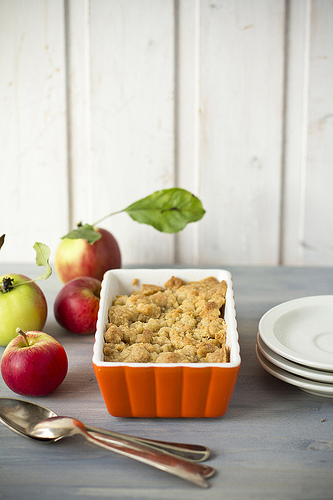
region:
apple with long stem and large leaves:
[54, 173, 207, 274]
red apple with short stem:
[0, 321, 65, 391]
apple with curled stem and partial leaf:
[0, 235, 51, 340]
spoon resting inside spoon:
[0, 393, 215, 486]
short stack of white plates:
[252, 285, 327, 398]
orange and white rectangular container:
[90, 263, 238, 412]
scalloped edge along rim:
[89, 264, 237, 364]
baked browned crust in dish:
[99, 271, 225, 364]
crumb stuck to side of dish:
[129, 270, 141, 288]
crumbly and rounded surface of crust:
[103, 274, 226, 362]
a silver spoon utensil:
[22, 417, 217, 486]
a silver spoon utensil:
[0, 395, 209, 462]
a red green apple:
[2, 325, 69, 396]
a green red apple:
[0, 271, 49, 350]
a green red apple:
[59, 227, 122, 282]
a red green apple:
[54, 277, 98, 334]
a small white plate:
[258, 294, 331, 373]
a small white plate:
[254, 329, 332, 383]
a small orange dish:
[90, 266, 239, 417]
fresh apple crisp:
[70, 247, 273, 438]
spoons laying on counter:
[0, 382, 215, 498]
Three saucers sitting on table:
[252, 279, 329, 440]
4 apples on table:
[0, 217, 123, 414]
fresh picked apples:
[0, 181, 97, 421]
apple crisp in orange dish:
[53, 215, 276, 442]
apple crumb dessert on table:
[90, 237, 251, 439]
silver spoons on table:
[0, 360, 234, 486]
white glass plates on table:
[250, 254, 329, 403]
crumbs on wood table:
[293, 394, 331, 465]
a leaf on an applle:
[127, 187, 204, 234]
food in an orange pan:
[99, 267, 240, 420]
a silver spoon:
[28, 416, 213, 490]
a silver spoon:
[0, 398, 210, 462]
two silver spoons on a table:
[0, 396, 215, 490]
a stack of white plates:
[256, 293, 331, 397]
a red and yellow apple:
[1, 329, 68, 394]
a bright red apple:
[53, 276, 100, 332]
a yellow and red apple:
[0, 275, 46, 340]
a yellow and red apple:
[58, 223, 121, 282]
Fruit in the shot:
[7, 207, 98, 416]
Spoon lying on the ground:
[0, 392, 244, 495]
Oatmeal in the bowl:
[88, 258, 249, 393]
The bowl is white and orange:
[93, 262, 253, 422]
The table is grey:
[230, 417, 325, 481]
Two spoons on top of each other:
[4, 395, 250, 492]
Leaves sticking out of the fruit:
[55, 188, 236, 248]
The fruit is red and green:
[2, 260, 92, 402]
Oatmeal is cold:
[96, 272, 237, 375]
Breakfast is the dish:
[14, 209, 268, 428]